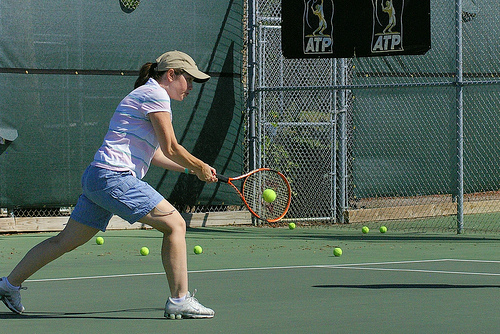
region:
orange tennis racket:
[194, 137, 316, 250]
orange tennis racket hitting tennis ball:
[210, 131, 319, 251]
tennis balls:
[283, 198, 418, 294]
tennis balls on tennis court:
[277, 198, 424, 280]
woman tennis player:
[53, 7, 341, 328]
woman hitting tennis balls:
[37, 9, 327, 331]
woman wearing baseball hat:
[46, 13, 239, 321]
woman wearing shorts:
[47, 7, 237, 254]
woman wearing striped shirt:
[37, 2, 229, 264]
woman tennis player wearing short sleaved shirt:
[59, 16, 331, 326]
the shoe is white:
[147, 276, 222, 322]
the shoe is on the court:
[155, 290, 215, 321]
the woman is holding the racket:
[0, 33, 305, 318]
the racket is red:
[217, 152, 302, 224]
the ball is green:
[258, 187, 285, 207]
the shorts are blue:
[63, 157, 163, 237]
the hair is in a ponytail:
[133, 55, 153, 90]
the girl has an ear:
[162, 65, 178, 90]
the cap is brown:
[147, 40, 217, 88]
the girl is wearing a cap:
[6, 29, 231, 326]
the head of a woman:
[135, 46, 205, 108]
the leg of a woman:
[93, 170, 195, 301]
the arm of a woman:
[147, 88, 198, 177]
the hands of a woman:
[193, 157, 220, 185]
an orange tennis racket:
[216, 157, 297, 227]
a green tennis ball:
[258, 182, 280, 206]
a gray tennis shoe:
[157, 285, 220, 322]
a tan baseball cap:
[148, 44, 215, 85]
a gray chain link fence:
[0, 1, 499, 243]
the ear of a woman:
[163, 63, 176, 85]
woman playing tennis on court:
[6, 40, 308, 324]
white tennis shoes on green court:
[148, 272, 227, 324]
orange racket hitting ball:
[221, 160, 301, 235]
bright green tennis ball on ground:
[327, 242, 346, 257]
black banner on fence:
[273, 1, 438, 65]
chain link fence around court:
[297, 80, 446, 189]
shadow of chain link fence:
[205, 22, 237, 85]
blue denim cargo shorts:
[61, 154, 165, 237]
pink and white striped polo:
[88, 75, 173, 190]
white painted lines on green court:
[366, 248, 428, 298]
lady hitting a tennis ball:
[102, 56, 289, 325]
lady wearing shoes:
[153, 284, 222, 324]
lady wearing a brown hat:
[161, 43, 206, 78]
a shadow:
[206, 58, 250, 123]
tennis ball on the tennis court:
[308, 231, 365, 260]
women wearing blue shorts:
[82, 164, 150, 216]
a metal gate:
[363, 109, 443, 189]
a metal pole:
[449, 82, 471, 237]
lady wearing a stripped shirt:
[107, 117, 149, 167]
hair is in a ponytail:
[125, 62, 156, 90]